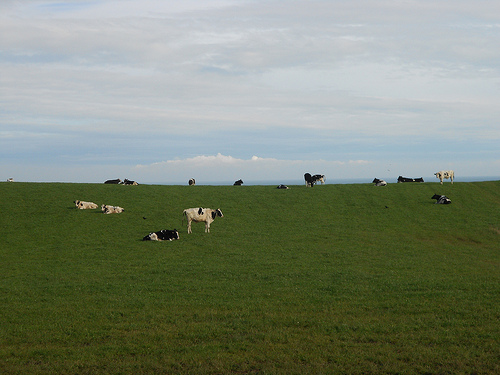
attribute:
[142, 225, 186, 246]
cow — white, black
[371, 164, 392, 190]
ground — green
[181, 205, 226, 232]
cows — together, Many 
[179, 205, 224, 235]
cow — white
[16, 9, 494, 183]
sun — shining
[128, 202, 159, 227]
bird — black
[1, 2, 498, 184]
sky — cloudy, blue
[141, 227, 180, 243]
cow — sitting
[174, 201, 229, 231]
cow — watching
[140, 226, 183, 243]
cow — watching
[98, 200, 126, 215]
cow — watching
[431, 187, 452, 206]
cow — watching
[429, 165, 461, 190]
cow — watching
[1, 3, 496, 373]
picture — Day time 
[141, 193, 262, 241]
cows — black, white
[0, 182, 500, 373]
grass — lush, green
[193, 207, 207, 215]
spots — black